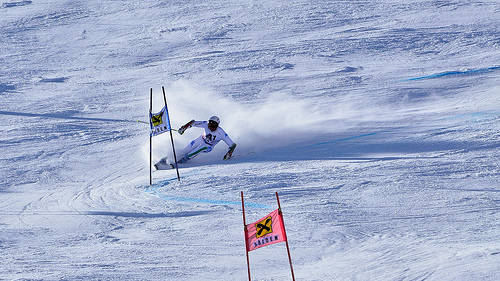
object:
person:
[154, 115, 237, 171]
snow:
[1, 1, 500, 280]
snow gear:
[169, 145, 216, 161]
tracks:
[19, 164, 144, 228]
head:
[208, 116, 221, 131]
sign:
[149, 86, 182, 188]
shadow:
[70, 209, 216, 218]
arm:
[221, 130, 235, 148]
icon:
[152, 113, 165, 126]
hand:
[228, 142, 238, 152]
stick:
[137, 86, 160, 193]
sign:
[241, 192, 296, 281]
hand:
[178, 127, 185, 135]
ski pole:
[146, 123, 174, 134]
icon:
[254, 217, 273, 238]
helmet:
[209, 116, 222, 123]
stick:
[161, 86, 181, 177]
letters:
[253, 234, 279, 248]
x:
[253, 216, 275, 235]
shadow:
[179, 140, 217, 164]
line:
[151, 190, 277, 209]